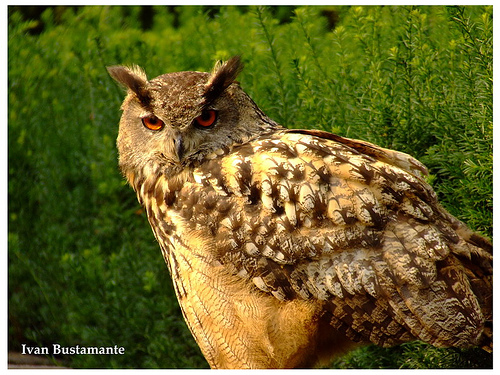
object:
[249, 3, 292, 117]
needles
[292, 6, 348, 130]
needles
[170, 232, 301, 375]
stomach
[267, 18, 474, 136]
object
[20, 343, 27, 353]
letter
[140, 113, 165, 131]
eye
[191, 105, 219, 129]
eye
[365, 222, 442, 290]
feather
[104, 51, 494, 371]
owl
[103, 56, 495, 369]
bird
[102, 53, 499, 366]
window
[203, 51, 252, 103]
ear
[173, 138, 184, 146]
nose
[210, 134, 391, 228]
wing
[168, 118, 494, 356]
feathers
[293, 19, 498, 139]
trees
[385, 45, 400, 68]
pine needle